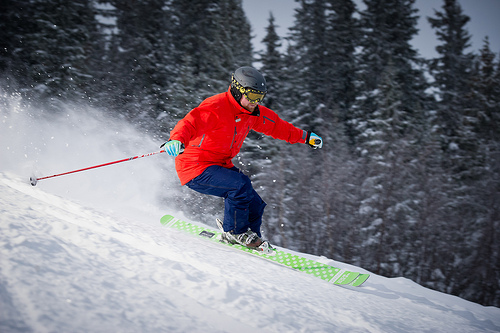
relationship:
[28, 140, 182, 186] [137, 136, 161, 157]
downhill ski pole with top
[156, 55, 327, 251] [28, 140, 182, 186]
man holds downhill ski pole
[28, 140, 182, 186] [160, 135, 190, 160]
downhill ski pole in hand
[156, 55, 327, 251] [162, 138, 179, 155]
man wearing blue & yellow gloves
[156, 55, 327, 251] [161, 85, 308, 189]
man in red jacket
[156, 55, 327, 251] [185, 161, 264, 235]
man in blue pair of pants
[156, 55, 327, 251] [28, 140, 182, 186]
man titled sideways on downhill ski pole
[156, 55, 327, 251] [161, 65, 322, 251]
man skiing man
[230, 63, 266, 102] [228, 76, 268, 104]
gray helmet on head with goggles on his face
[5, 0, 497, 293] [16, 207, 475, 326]
snow-capped trees behind snow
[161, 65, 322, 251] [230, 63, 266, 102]
man wearing gray helmet on head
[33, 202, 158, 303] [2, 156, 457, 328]
snow on mountain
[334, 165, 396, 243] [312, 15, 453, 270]
snow covered trees